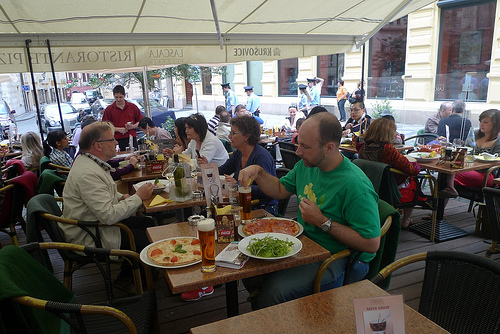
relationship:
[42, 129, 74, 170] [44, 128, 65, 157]
woman with hair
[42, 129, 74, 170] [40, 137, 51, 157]
woman with ponytail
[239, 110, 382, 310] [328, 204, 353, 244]
man wearing watch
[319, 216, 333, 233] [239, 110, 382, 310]
wrist belonging to man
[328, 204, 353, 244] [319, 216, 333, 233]
watch worn on wrist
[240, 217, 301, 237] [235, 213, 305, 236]
pizza lying on plate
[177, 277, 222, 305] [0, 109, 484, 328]
shoe standing on ground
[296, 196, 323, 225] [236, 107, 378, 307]
hand belonging to man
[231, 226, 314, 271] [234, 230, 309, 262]
salad on plate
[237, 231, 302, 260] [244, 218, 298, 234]
plate of food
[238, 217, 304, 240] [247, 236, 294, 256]
plate of food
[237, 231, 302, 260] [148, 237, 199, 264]
plate of food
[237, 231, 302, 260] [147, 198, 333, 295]
plate on table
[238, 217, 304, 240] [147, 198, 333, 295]
plate on table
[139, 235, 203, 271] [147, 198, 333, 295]
plate on table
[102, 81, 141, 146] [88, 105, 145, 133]
waiter in shirt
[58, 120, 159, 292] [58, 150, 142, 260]
man in shirt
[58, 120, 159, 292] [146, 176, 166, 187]
man eating food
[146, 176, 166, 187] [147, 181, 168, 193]
food from bowl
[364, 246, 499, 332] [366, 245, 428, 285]
chair with cane arms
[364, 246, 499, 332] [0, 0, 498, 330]
chair in restaurant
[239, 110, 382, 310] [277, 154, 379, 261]
man in shirt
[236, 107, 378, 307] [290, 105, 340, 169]
man has head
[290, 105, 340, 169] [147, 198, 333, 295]
head looking down at table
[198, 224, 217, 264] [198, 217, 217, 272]
liquid in glass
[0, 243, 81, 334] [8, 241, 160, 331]
jacket on back of chair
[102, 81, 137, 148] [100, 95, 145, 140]
man wearing polo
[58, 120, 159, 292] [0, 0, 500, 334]
man at table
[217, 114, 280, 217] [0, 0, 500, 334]
woman at table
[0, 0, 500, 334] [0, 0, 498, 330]
table at restaurant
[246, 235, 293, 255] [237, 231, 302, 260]
vegetables on plate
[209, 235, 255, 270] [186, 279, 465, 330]
book on table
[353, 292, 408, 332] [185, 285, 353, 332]
menu on table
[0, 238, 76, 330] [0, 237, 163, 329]
jacket on chair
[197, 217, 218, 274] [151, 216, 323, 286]
beer on table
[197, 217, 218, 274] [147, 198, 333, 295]
beer on table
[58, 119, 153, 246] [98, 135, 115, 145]
man wearing glasses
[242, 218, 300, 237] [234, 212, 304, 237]
pizza on plate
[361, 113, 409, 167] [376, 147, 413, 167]
woman wearing red shirt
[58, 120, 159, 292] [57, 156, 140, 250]
man wearing jacket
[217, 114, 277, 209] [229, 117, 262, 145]
woman with curly hair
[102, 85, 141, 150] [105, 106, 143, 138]
waiter wearing shirt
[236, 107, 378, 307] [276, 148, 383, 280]
man in shirt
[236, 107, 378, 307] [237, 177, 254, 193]
man squeezing lemon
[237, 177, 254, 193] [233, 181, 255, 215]
lemon in drink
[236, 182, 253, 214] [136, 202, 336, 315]
drinks on table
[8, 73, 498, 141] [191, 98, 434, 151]
police walking down street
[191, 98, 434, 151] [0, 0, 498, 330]
street outside restaurant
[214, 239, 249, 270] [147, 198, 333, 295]
menu on table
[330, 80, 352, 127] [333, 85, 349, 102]
lady in shirt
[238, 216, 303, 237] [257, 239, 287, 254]
plate with food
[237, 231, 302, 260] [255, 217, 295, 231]
plate with food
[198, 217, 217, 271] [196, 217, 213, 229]
glass with foam head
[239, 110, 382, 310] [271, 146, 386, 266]
man in shirt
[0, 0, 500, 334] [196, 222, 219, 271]
table with beer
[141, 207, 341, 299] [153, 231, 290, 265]
table with food